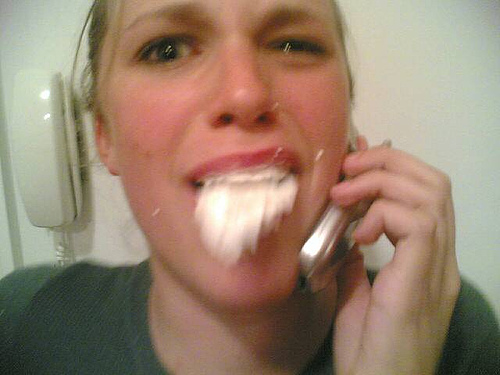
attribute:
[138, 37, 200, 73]
eye — squinted, almost shut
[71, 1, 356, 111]
hair — pulled back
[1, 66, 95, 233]
phone — white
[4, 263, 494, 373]
shirt — green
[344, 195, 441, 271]
pinky finger — pink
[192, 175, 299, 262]
foam — white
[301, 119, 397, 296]
phone — white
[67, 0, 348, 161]
hair — blonde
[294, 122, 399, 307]
cellphone — silver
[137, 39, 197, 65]
eye — dark green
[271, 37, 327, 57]
eye — dark green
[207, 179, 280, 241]
stuff — white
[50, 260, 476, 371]
shirt — green